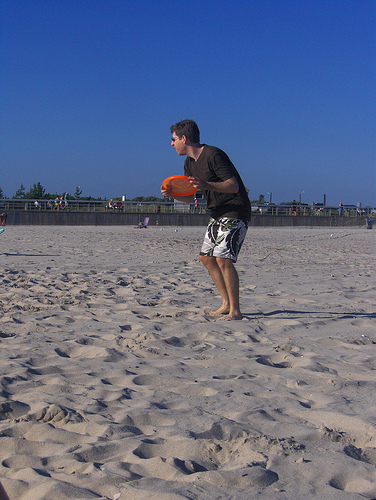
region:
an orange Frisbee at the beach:
[161, 174, 198, 196]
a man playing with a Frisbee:
[159, 119, 251, 323]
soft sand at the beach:
[1, 223, 375, 498]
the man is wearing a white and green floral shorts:
[200, 216, 247, 263]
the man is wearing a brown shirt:
[185, 144, 252, 217]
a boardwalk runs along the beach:
[0, 192, 375, 227]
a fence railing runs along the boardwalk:
[0, 197, 375, 215]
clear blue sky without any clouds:
[0, 0, 374, 200]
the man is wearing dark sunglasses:
[170, 134, 187, 141]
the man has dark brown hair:
[169, 118, 200, 143]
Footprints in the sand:
[10, 313, 296, 485]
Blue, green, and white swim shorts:
[181, 196, 258, 259]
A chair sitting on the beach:
[123, 212, 172, 239]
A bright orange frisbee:
[153, 163, 213, 212]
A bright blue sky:
[15, 71, 360, 226]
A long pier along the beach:
[1, 185, 372, 231]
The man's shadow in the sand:
[243, 304, 372, 324]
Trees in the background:
[20, 161, 74, 207]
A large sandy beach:
[7, 226, 374, 433]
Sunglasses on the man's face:
[165, 127, 187, 146]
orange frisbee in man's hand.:
[173, 178, 190, 191]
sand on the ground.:
[200, 357, 247, 377]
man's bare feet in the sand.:
[211, 301, 253, 336]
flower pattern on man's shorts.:
[212, 226, 243, 255]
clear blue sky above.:
[278, 112, 329, 151]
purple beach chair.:
[138, 216, 150, 228]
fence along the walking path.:
[61, 203, 128, 220]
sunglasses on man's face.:
[169, 136, 180, 146]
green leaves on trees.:
[24, 183, 40, 195]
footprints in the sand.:
[39, 269, 112, 292]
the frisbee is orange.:
[154, 162, 212, 218]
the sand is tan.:
[59, 272, 324, 498]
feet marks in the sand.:
[19, 223, 360, 498]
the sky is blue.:
[18, 9, 369, 138]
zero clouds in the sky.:
[7, 13, 364, 190]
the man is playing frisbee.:
[154, 125, 280, 315]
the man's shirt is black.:
[138, 126, 259, 274]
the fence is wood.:
[7, 171, 374, 229]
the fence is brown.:
[8, 183, 361, 246]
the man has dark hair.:
[161, 114, 197, 161]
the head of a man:
[167, 113, 202, 160]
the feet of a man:
[204, 294, 243, 327]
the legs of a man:
[199, 213, 250, 307]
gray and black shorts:
[195, 214, 253, 260]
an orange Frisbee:
[160, 167, 202, 205]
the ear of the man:
[179, 131, 189, 146]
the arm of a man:
[203, 145, 238, 203]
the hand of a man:
[185, 173, 212, 196]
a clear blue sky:
[1, 0, 374, 209]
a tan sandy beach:
[1, 225, 374, 497]